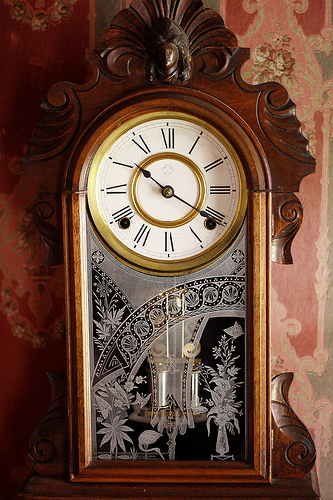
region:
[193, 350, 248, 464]
a design on the clock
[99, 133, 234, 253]
a clock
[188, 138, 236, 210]
roman numerials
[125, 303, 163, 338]
white design on the clock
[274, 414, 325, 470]
wood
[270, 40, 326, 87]
the wallpaper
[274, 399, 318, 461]
the design on the wood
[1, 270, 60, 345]
design on the wallpaper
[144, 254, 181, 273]
the rim of the clock is gold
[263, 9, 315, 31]
wallpaper is red and pink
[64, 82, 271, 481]
An unpright grandfather clock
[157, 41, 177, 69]
A carved face on the clock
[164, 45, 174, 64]
Refelction of light on the face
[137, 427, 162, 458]
A white bird looking down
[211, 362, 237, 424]
A bunch of flower in a vase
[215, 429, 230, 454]
A fVase with flowers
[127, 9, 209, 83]
The clock's wood carving decoration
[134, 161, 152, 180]
The black hour hand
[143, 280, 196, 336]
Decoration on the glass window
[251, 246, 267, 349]
Light cast on the clock frame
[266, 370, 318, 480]
An intricate carving on the side of a clock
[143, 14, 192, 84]
A carved head on top of a clock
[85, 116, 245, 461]
A clock display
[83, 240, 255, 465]
White designs on a glass panel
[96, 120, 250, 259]
A white clock face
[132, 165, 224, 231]
The two hands of a clock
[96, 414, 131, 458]
A white plant on glass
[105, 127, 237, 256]
A clock with Roman numerals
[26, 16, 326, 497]
A clock surrounded by a wooden carving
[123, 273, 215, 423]
The inner workings of a clock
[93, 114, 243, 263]
the white face of a clock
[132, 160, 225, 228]
the black hands of a clock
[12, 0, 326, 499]
a brown wooden clock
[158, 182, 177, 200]
the center of a clock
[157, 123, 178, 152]
a number on the clock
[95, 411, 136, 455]
a flower on the clock window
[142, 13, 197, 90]
a figure head on the clock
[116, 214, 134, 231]
a wind-up slot on the clock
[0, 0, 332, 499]
an ornate red wall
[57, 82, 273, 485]
the frame of the clock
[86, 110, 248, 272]
traditional clock face with roman numerals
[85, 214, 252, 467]
intricately etched glass on a clock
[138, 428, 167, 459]
a stork etched in glass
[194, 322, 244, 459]
flowers in a vase etched in glass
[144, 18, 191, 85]
decorative carving of a face on top of a clock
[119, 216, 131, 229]
keyhole on a clock to wind it up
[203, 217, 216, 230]
keyhole in a clock face to set the time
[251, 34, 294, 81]
flower pattern on wallpaper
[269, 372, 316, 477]
decorative swirl carved in wood to accent a clock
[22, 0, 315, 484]
antique and intrically carved mantle clock